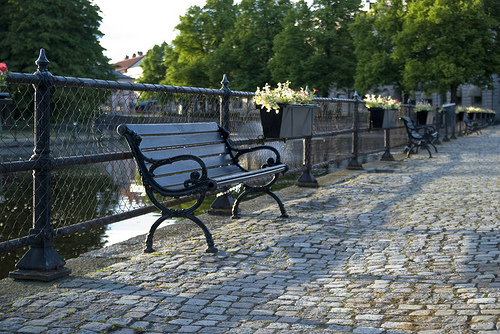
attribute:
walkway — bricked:
[0, 117, 498, 329]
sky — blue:
[113, 11, 155, 33]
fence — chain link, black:
[3, 48, 499, 258]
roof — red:
[111, 52, 146, 72]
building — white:
[111, 50, 149, 94]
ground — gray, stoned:
[268, 238, 348, 302]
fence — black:
[48, 66, 127, 153]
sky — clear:
[87, 4, 197, 64]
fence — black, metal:
[3, 52, 493, 275]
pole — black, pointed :
[14, 43, 65, 273]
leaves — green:
[264, 17, 359, 93]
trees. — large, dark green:
[181, 9, 444, 99]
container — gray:
[260, 103, 312, 137]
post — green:
[17, 52, 73, 289]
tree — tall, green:
[1, 1, 115, 126]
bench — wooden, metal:
[131, 120, 265, 235]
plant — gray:
[251, 76, 323, 116]